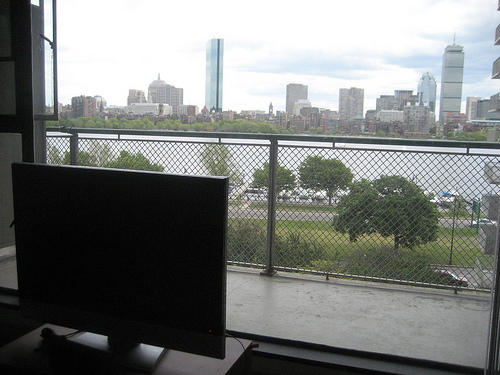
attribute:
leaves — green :
[333, 165, 350, 182]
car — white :
[473, 216, 498, 231]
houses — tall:
[112, 36, 469, 120]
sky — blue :
[413, 59, 432, 69]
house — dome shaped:
[144, 73, 170, 90]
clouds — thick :
[245, 1, 375, 93]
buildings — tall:
[286, 38, 466, 124]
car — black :
[426, 258, 471, 292]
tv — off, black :
[11, 161, 228, 373]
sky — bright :
[47, 1, 494, 107]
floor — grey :
[222, 270, 484, 354]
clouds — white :
[255, 7, 440, 65]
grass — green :
[296, 200, 429, 287]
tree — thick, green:
[337, 173, 449, 253]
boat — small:
[437, 181, 469, 214]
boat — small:
[410, 179, 444, 214]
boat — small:
[326, 174, 353, 206]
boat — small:
[307, 185, 331, 207]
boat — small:
[293, 182, 315, 207]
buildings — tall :
[66, 25, 493, 137]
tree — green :
[335, 172, 438, 249]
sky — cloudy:
[28, 5, 498, 120]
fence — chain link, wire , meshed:
[34, 120, 498, 304]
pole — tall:
[448, 27, 463, 52]